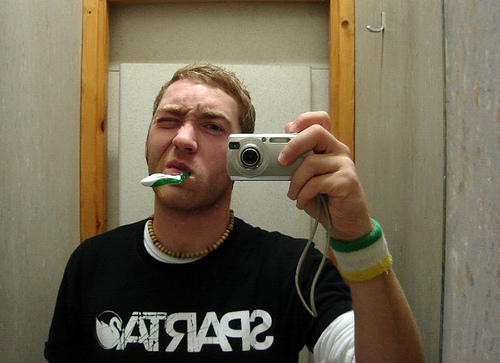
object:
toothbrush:
[138, 171, 191, 188]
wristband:
[325, 216, 393, 285]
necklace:
[146, 208, 235, 259]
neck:
[153, 182, 232, 253]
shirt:
[43, 215, 354, 352]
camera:
[225, 131, 317, 181]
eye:
[154, 116, 182, 123]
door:
[140, 17, 210, 61]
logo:
[93, 309, 126, 349]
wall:
[461, 21, 484, 163]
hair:
[179, 64, 218, 79]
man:
[43, 60, 428, 363]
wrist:
[322, 217, 390, 253]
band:
[328, 216, 384, 253]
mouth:
[163, 158, 196, 179]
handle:
[364, 11, 386, 33]